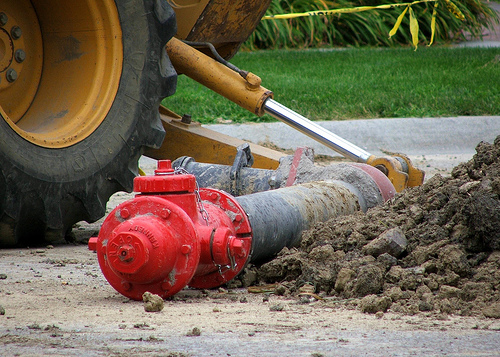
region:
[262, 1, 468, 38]
caution tape is tied in a knot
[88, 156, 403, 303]
fire hydrant is laying on it's side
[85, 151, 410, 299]
fire hydrant has a red cap on top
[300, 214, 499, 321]
chunks of rock mixed in the dirt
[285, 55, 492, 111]
luscious green grass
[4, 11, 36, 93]
three bolts in a curved line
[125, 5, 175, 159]
tire has large grooves for a good grip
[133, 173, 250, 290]
red cap has chain connected to it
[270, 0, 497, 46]
foliage is behind the caution tape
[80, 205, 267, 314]
small rocks lying near hydrant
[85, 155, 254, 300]
a fire hydrant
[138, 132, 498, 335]
dirt on ground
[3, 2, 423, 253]
a yellow crane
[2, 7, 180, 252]
the huge wheel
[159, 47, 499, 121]
the grass on side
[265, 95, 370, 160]
the steel on crane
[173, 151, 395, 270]
the pipe of hydrant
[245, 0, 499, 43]
the plants by grass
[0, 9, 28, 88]
bolts on tire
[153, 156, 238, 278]
chain on hydrant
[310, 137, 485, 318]
a pile of dirt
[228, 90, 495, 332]
a pile of dirt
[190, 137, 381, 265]
the pipe is dirty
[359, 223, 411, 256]
large clump of dirt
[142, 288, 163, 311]
small clup of dirt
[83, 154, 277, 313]
red fire hydrant attached to a silver pole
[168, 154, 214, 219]
chain on the hydrant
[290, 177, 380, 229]
dirt on the pole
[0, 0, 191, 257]
black and yellow tire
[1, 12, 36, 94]
bolts on the tire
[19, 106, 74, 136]
yellow paint is peeling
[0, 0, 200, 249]
thick black tire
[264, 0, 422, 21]
piece of bright yellow caution tape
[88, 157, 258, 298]
bright red cap of metal pipe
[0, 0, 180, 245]
large black and yellow truck tire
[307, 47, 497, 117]
small green section of manufactured lawn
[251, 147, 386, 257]
section of grey metal pipe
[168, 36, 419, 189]
metal and bright yellow truck brace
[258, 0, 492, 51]
green and yellow fern leaves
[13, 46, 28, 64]
large grey lug nut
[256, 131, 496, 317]
dark brown pile of dirt and rock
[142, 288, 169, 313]
small clump of dirt and rock